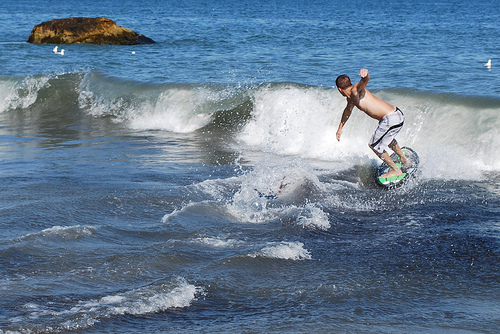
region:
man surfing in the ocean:
[327, 69, 428, 194]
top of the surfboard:
[374, 144, 418, 196]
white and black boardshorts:
[368, 107, 400, 157]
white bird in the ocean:
[483, 57, 498, 71]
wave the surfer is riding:
[14, 65, 499, 167]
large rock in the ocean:
[27, 10, 144, 42]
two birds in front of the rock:
[45, 44, 68, 61]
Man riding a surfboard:
[331, 67, 421, 194]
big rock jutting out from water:
[28, 15, 153, 45]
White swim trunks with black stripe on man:
[369, 106, 404, 157]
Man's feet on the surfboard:
[377, 144, 417, 192]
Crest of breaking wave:
[0, 69, 497, 173]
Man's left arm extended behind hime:
[356, 65, 374, 90]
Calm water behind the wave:
[0, 0, 498, 77]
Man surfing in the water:
[331, 66, 419, 194]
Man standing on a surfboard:
[331, 68, 421, 191]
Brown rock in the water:
[28, 14, 155, 49]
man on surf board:
[304, 57, 417, 199]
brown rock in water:
[22, 15, 145, 52]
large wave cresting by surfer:
[20, 71, 438, 154]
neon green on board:
[380, 153, 402, 193]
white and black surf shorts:
[362, 100, 407, 160]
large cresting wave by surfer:
[198, 81, 428, 155]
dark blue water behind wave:
[223, 8, 352, 63]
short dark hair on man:
[332, 68, 352, 95]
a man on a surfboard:
[322, 64, 427, 188]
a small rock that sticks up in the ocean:
[24, 17, 164, 57]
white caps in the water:
[72, 140, 379, 324]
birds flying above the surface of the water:
[40, 43, 498, 74]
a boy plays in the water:
[327, 71, 429, 188]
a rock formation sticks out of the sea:
[27, 14, 172, 55]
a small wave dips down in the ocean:
[4, 74, 496, 188]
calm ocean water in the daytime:
[155, 15, 470, 63]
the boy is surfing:
[302, 48, 433, 253]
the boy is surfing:
[314, 52, 445, 239]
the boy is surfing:
[315, 54, 432, 234]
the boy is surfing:
[310, 48, 427, 243]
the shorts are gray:
[368, 103, 408, 163]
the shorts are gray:
[360, 100, 404, 162]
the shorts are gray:
[365, 96, 417, 164]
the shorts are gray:
[362, 95, 408, 157]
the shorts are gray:
[360, 102, 411, 165]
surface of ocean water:
[2, 1, 497, 82]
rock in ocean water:
[28, 16, 158, 46]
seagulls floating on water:
[50, 44, 64, 55]